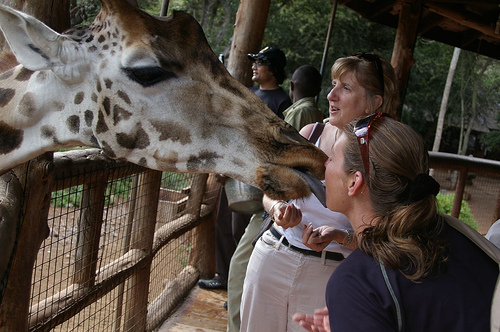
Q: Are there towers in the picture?
A: No, there are no towers.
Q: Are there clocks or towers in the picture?
A: No, there are no towers or clocks.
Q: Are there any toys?
A: No, there are no toys.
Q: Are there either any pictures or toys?
A: No, there are no toys or pictures.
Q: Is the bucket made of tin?
A: Yes, the bucket is made of tin.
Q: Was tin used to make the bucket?
A: Yes, the bucket is made of tin.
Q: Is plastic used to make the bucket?
A: No, the bucket is made of tin.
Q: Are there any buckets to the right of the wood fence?
A: Yes, there is a bucket to the right of the fence.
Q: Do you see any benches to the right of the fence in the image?
A: No, there is a bucket to the right of the fence.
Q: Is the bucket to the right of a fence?
A: Yes, the bucket is to the right of a fence.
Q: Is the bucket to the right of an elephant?
A: No, the bucket is to the right of a fence.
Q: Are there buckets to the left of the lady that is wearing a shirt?
A: Yes, there is a bucket to the left of the lady.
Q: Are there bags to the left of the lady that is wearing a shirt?
A: No, there is a bucket to the left of the lady.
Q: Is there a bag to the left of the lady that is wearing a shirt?
A: No, there is a bucket to the left of the lady.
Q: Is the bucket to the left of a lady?
A: Yes, the bucket is to the left of a lady.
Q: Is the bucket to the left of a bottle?
A: No, the bucket is to the left of a lady.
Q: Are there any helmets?
A: No, there are no helmets.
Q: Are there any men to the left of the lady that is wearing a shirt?
A: Yes, there is a man to the left of the lady.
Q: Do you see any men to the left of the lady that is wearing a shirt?
A: Yes, there is a man to the left of the lady.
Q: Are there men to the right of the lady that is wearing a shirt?
A: No, the man is to the left of the lady.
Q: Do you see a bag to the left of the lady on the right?
A: No, there is a man to the left of the lady.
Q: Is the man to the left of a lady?
A: Yes, the man is to the left of a lady.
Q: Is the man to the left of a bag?
A: No, the man is to the left of a lady.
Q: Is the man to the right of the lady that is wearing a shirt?
A: No, the man is to the left of the lady.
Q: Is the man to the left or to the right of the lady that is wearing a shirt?
A: The man is to the left of the lady.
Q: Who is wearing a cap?
A: The man is wearing a cap.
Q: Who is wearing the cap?
A: The man is wearing a cap.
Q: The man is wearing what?
A: The man is wearing a cap.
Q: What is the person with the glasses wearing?
A: The man is wearing a cap.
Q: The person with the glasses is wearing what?
A: The man is wearing a cap.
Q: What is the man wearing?
A: The man is wearing a cap.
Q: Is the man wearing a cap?
A: Yes, the man is wearing a cap.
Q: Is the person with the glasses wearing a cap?
A: Yes, the man is wearing a cap.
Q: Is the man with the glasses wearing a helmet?
A: No, the man is wearing a cap.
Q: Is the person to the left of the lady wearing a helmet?
A: No, the man is wearing a cap.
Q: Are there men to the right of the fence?
A: Yes, there is a man to the right of the fence.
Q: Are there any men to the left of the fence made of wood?
A: No, the man is to the right of the fence.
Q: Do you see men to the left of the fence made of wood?
A: No, the man is to the right of the fence.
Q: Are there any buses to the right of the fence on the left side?
A: No, there is a man to the right of the fence.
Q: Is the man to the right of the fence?
A: Yes, the man is to the right of the fence.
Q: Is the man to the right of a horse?
A: No, the man is to the right of the fence.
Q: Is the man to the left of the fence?
A: No, the man is to the right of the fence.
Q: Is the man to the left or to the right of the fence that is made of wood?
A: The man is to the right of the fence.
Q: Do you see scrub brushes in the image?
A: No, there are no scrub brushes.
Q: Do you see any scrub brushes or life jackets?
A: No, there are no scrub brushes or life jackets.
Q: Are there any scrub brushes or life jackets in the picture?
A: No, there are no scrub brushes or life jackets.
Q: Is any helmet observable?
A: No, there are no helmets.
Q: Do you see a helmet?
A: No, there are no helmets.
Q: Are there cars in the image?
A: No, there are no cars.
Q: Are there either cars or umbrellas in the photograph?
A: No, there are no cars or umbrellas.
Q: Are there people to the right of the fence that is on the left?
A: Yes, there are people to the right of the fence.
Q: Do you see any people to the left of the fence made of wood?
A: No, the people are to the right of the fence.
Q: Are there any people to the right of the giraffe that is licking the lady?
A: Yes, there are people to the right of the giraffe.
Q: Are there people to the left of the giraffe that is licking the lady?
A: No, the people are to the right of the giraffe.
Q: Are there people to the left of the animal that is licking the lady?
A: No, the people are to the right of the giraffe.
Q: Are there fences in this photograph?
A: Yes, there is a fence.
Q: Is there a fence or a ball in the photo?
A: Yes, there is a fence.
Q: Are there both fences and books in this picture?
A: No, there is a fence but no books.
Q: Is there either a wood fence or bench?
A: Yes, there is a wood fence.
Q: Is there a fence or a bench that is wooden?
A: Yes, the fence is wooden.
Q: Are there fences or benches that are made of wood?
A: Yes, the fence is made of wood.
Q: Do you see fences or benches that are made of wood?
A: Yes, the fence is made of wood.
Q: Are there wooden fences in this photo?
A: Yes, there is a wood fence.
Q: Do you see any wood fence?
A: Yes, there is a wood fence.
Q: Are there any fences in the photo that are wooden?
A: Yes, there is a fence that is wooden.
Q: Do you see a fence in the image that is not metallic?
A: Yes, there is a wooden fence.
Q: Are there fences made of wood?
A: Yes, there is a fence that is made of wood.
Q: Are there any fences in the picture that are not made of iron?
A: Yes, there is a fence that is made of wood.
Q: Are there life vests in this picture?
A: No, there are no life vests.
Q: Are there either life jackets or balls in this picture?
A: No, there are no life jackets or balls.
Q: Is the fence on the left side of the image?
A: Yes, the fence is on the left of the image.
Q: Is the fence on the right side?
A: No, the fence is on the left of the image.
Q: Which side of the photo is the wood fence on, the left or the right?
A: The fence is on the left of the image.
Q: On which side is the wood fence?
A: The fence is on the left of the image.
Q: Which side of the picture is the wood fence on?
A: The fence is on the left of the image.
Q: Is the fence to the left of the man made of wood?
A: Yes, the fence is made of wood.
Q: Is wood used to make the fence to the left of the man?
A: Yes, the fence is made of wood.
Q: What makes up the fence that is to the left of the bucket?
A: The fence is made of wood.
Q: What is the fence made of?
A: The fence is made of wood.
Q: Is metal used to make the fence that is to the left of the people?
A: No, the fence is made of wood.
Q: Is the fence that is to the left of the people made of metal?
A: No, the fence is made of wood.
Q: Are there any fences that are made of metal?
A: No, there is a fence but it is made of wood.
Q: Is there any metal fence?
A: No, there is a fence but it is made of wood.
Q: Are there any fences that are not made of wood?
A: No, there is a fence but it is made of wood.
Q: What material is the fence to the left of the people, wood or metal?
A: The fence is made of wood.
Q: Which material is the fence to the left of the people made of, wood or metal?
A: The fence is made of wood.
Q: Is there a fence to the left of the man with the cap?
A: Yes, there is a fence to the left of the man.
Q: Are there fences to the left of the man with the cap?
A: Yes, there is a fence to the left of the man.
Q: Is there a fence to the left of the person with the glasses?
A: Yes, there is a fence to the left of the man.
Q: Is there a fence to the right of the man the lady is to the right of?
A: No, the fence is to the left of the man.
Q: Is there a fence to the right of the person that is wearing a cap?
A: No, the fence is to the left of the man.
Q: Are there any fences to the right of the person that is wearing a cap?
A: No, the fence is to the left of the man.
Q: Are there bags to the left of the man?
A: No, there is a fence to the left of the man.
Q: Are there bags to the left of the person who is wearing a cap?
A: No, there is a fence to the left of the man.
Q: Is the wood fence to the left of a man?
A: Yes, the fence is to the left of a man.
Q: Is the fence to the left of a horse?
A: No, the fence is to the left of a man.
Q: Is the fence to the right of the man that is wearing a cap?
A: No, the fence is to the left of the man.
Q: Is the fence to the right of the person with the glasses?
A: No, the fence is to the left of the man.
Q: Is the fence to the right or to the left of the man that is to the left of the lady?
A: The fence is to the left of the man.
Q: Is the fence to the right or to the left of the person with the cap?
A: The fence is to the left of the man.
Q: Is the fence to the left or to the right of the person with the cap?
A: The fence is to the left of the man.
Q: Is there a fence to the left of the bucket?
A: Yes, there is a fence to the left of the bucket.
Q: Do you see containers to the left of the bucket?
A: No, there is a fence to the left of the bucket.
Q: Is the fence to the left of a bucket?
A: Yes, the fence is to the left of a bucket.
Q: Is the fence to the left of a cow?
A: No, the fence is to the left of a bucket.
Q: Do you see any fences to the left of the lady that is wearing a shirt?
A: Yes, there is a fence to the left of the lady.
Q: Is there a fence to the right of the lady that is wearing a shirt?
A: No, the fence is to the left of the lady.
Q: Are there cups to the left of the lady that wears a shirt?
A: No, there is a fence to the left of the lady.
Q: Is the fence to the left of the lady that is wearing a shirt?
A: Yes, the fence is to the left of the lady.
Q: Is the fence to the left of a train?
A: No, the fence is to the left of the lady.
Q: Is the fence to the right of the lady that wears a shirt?
A: No, the fence is to the left of the lady.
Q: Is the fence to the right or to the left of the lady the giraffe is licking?
A: The fence is to the left of the lady.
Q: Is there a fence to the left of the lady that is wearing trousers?
A: Yes, there is a fence to the left of the lady.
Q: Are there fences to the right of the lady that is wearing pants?
A: No, the fence is to the left of the lady.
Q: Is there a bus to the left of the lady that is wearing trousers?
A: No, there is a fence to the left of the lady.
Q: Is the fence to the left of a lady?
A: Yes, the fence is to the left of a lady.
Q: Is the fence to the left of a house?
A: No, the fence is to the left of a lady.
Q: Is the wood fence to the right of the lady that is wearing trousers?
A: No, the fence is to the left of the lady.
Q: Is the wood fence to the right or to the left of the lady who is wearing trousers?
A: The fence is to the left of the lady.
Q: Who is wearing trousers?
A: The lady is wearing trousers.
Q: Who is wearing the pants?
A: The lady is wearing trousers.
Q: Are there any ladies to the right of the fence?
A: Yes, there is a lady to the right of the fence.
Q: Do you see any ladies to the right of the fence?
A: Yes, there is a lady to the right of the fence.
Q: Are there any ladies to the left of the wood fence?
A: No, the lady is to the right of the fence.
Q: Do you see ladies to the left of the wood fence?
A: No, the lady is to the right of the fence.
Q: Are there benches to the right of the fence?
A: No, there is a lady to the right of the fence.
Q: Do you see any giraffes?
A: Yes, there is a giraffe.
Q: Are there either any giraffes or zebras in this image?
A: Yes, there is a giraffe.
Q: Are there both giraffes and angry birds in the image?
A: No, there is a giraffe but no angry birds.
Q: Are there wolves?
A: No, there are no wolves.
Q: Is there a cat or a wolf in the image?
A: No, there are no wolves or cats.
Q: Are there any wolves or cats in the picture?
A: No, there are no wolves or cats.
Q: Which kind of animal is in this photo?
A: The animal is a giraffe.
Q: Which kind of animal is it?
A: The animal is a giraffe.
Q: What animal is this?
A: This is a giraffe.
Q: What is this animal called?
A: This is a giraffe.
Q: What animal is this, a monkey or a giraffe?
A: This is a giraffe.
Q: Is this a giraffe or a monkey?
A: This is a giraffe.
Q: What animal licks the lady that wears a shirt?
A: The giraffe licks the lady.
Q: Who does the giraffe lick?
A: The giraffe licks the lady.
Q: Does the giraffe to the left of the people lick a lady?
A: Yes, the giraffe licks a lady.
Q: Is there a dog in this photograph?
A: No, there are no dogs.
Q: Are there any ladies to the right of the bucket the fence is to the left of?
A: Yes, there is a lady to the right of the bucket.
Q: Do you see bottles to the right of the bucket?
A: No, there is a lady to the right of the bucket.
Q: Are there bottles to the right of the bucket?
A: No, there is a lady to the right of the bucket.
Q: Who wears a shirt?
A: The lady wears a shirt.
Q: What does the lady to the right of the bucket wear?
A: The lady wears a shirt.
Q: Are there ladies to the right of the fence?
A: Yes, there is a lady to the right of the fence.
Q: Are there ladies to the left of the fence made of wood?
A: No, the lady is to the right of the fence.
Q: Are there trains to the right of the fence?
A: No, there is a lady to the right of the fence.